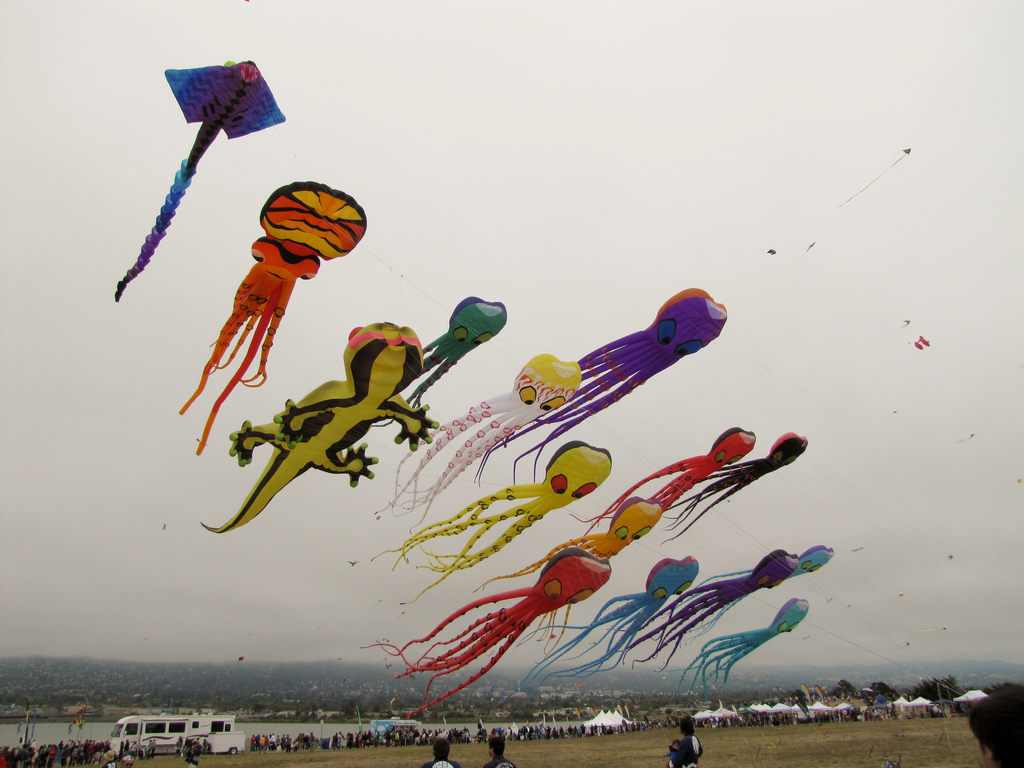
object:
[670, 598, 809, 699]
kite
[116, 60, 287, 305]
kite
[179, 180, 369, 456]
kite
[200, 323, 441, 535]
kite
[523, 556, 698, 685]
kite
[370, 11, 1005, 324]
sky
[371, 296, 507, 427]
kite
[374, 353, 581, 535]
kite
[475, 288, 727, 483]
kite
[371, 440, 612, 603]
kite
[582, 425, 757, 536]
kite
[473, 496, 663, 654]
kite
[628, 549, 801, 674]
kite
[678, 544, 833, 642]
kite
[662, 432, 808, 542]
kite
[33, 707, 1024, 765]
field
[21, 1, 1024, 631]
background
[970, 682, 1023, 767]
head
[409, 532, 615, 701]
kite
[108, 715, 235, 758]
rv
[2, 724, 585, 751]
river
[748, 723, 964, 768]
grass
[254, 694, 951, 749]
crowd